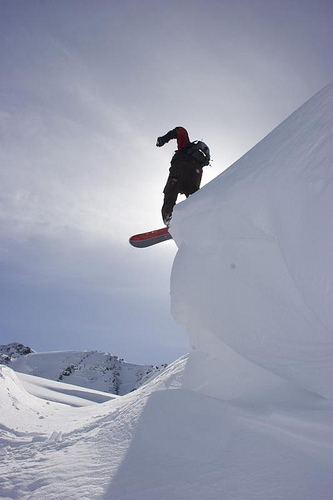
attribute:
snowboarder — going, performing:
[119, 117, 219, 257]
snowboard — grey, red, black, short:
[123, 219, 185, 260]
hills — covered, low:
[2, 338, 176, 408]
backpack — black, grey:
[172, 138, 201, 192]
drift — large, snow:
[115, 75, 331, 407]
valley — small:
[8, 380, 127, 435]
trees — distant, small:
[56, 347, 127, 394]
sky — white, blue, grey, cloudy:
[4, 0, 331, 371]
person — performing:
[123, 125, 226, 263]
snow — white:
[3, 65, 328, 499]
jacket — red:
[154, 123, 225, 190]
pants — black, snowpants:
[161, 176, 201, 229]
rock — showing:
[1, 343, 35, 370]